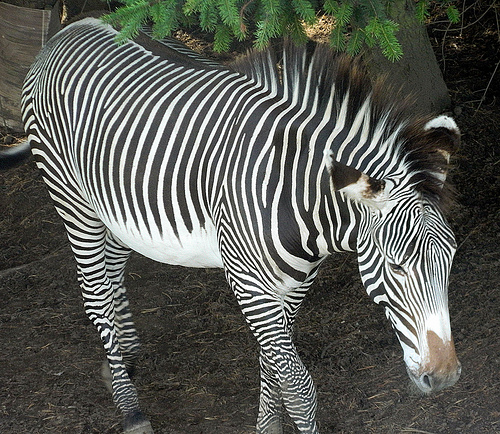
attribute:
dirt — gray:
[335, 306, 383, 410]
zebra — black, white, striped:
[21, 15, 461, 430]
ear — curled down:
[323, 151, 387, 208]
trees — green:
[98, 2, 461, 58]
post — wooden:
[0, 8, 63, 152]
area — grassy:
[0, 49, 490, 429]